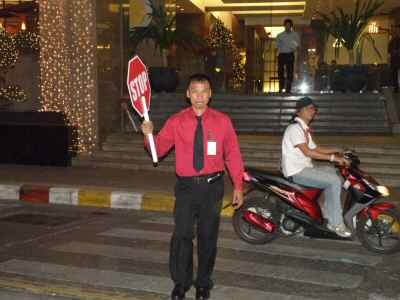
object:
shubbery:
[0, 23, 40, 103]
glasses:
[300, 106, 318, 114]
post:
[39, 0, 97, 156]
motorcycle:
[222, 143, 400, 255]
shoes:
[170, 285, 192, 300]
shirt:
[142, 105, 244, 192]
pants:
[167, 169, 225, 292]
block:
[19, 184, 54, 205]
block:
[77, 186, 113, 209]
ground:
[0, 162, 399, 299]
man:
[137, 72, 245, 298]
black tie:
[192, 114, 205, 173]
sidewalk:
[0, 164, 399, 233]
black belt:
[175, 170, 226, 185]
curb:
[0, 182, 399, 231]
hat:
[295, 96, 313, 109]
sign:
[126, 53, 158, 163]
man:
[278, 96, 353, 238]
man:
[272, 18, 302, 95]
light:
[368, 21, 379, 35]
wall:
[300, 0, 391, 66]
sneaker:
[326, 220, 353, 238]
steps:
[70, 93, 400, 188]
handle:
[141, 96, 159, 164]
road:
[0, 196, 399, 298]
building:
[0, 0, 399, 188]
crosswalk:
[0, 210, 399, 299]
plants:
[128, 0, 213, 93]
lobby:
[203, 0, 390, 95]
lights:
[75, 67, 81, 73]